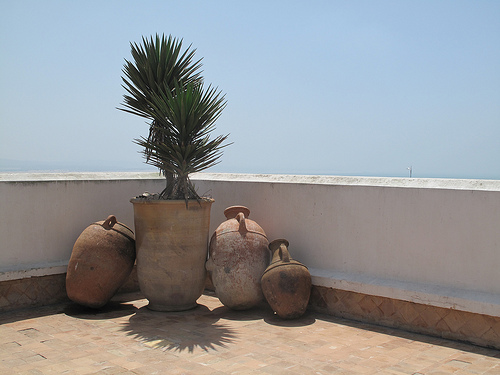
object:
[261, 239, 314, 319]
pot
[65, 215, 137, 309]
pot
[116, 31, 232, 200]
plant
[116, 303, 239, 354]
shadow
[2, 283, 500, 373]
ground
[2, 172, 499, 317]
wall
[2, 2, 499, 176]
sky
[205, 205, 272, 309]
pot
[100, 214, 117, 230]
handle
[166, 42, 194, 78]
leaf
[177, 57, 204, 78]
leaf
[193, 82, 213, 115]
leaf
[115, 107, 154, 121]
leaf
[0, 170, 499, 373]
balcony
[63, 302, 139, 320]
shadow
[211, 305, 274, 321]
shadow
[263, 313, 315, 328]
shadow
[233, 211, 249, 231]
handle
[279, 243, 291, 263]
handle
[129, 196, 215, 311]
pot